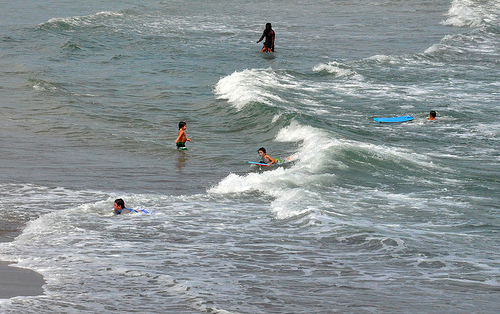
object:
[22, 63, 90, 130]
water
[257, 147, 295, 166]
kid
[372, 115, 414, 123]
board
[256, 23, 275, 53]
man